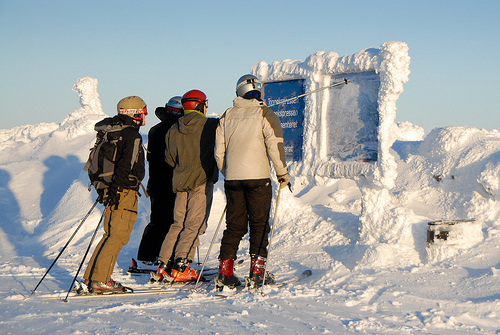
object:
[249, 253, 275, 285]
boot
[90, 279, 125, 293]
boot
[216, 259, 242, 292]
boot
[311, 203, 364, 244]
shade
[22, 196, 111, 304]
ski poles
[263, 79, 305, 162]
board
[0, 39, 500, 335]
snow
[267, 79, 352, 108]
ski pole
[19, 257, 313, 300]
skis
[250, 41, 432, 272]
sculpture made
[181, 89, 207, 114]
red helmet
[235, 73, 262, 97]
silver helmet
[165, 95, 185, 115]
blue helmet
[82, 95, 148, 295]
man wearing khaki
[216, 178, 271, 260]
black pants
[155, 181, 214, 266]
gray pants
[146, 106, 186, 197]
black jacket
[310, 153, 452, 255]
covered in snow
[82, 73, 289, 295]
standing in the snow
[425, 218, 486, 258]
boot used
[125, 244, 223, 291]
boot used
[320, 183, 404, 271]
boot used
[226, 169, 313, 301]
boot for skiing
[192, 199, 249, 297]
boot for skiing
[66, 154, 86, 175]
part of a shade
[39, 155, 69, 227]
part of a shade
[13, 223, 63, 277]
part of a shade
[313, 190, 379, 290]
part of a hooker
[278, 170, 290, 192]
part of a hooker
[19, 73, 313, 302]
people wearing skiis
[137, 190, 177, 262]
black pants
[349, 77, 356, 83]
pole to point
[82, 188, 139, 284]
green pants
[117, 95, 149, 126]
green helmet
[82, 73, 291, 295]
four people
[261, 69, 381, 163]
blue and white sign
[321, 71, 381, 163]
snow-covered sign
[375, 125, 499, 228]
snow-covered slope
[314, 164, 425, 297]
snow-covered slope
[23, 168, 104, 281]
snow-covered slope